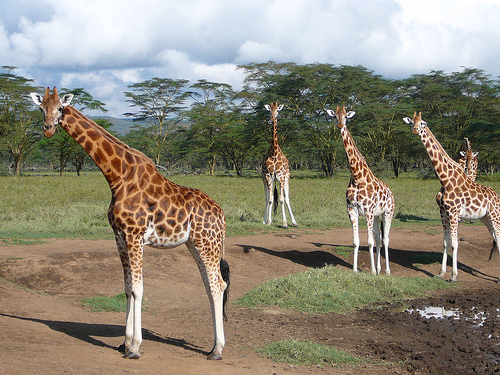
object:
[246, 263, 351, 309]
grass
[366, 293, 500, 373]
mud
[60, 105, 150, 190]
neck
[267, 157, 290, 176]
spots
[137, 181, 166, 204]
spots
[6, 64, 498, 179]
trees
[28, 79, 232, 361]
blue mini-van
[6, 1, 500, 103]
cloud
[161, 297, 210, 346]
dirt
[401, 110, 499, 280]
giraffe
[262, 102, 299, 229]
giraffe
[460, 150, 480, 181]
giraffe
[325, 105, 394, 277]
giraffe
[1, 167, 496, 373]
field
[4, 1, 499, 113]
sky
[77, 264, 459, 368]
dirt patches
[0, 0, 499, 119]
blue sky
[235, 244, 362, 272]
shadow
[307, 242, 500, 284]
shadow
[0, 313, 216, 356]
shadow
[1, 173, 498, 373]
ground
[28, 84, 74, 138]
head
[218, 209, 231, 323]
tail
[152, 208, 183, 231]
spots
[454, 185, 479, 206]
spots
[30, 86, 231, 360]
giraffe